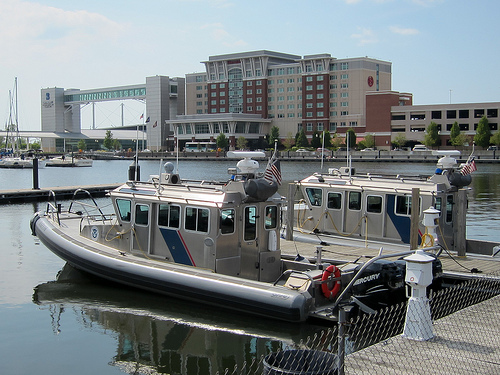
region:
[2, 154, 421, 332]
the boat is on the water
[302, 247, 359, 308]
the life saver is on the back of the boat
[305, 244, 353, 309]
the life saver is red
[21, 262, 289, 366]
the water is reflecting the boat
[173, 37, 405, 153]
a building in the background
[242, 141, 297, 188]
the flag is red, white, and blue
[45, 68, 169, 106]
a walkway in the middle of the buildings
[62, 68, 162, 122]
the walkway is above the street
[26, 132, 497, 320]
Two similar boats docked by a pier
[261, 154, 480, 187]
Two American flags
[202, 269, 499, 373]
Grey metal chainlink fence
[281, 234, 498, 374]
Wooden dock over the water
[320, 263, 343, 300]
Red life preserver on back of boat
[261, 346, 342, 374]
Round metal garbage can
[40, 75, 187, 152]
Overhead walkway between rectangular buildings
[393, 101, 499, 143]
Parking garage on the right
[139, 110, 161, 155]
Poles with flags in front of a building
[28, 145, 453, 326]
silver boat on water at dock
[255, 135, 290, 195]
flag on top of silver boat at the dock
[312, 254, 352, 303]
red life float on the back of silver boat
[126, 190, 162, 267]
door on the left side of silver boat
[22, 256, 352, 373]
reflection of silver boat in the water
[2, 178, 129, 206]
wooden pier in middle of water in front of boat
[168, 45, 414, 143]
beige and red brick building in back of picture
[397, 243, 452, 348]
white pump on wooden pier behind boat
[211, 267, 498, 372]
metal fence behind the silver boat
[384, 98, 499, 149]
beige parking deck next to brick building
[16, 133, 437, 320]
Boat is in the water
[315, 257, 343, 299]
Life raft on the back of a boat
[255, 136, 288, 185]
American flag on a boat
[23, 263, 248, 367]
Reflection of a boat in the water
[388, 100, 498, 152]
Multi story parking lot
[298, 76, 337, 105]
Windows on the side of a building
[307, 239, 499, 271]
Boardwalk to get to the boats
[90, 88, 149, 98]
Glass windows on a building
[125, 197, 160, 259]
Door on a boat in the water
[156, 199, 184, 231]
Windows of a boat in the water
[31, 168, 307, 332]
A big ship in water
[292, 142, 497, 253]
A big ship in water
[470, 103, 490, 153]
A short green tree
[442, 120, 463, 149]
A short green tree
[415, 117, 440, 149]
A short green tree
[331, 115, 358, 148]
A short green tree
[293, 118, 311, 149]
A short green tree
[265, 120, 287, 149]
A short green tree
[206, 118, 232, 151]
A short green tree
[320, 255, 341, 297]
life saver on the boat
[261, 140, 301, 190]
american flag on the boat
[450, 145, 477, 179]
american flag on the boat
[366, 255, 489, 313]
black engine on the boat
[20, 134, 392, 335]
boat parked in the pier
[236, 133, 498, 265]
boat parked in the pier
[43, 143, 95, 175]
boat parked in the pier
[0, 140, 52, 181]
boat parked in the pier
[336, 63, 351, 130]
row of window on the hotel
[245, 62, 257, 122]
row of window on the hotel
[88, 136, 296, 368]
a boat in the water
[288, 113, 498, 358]
a boat in the water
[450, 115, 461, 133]
green leaves on the tree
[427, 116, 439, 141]
green leaves on the tree